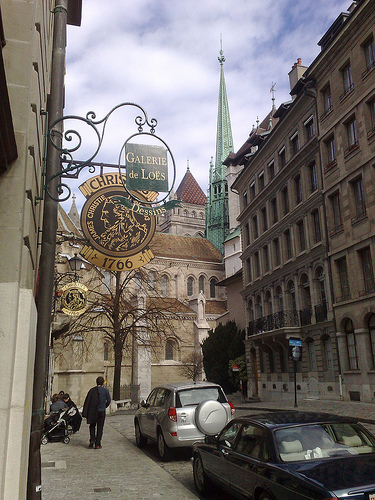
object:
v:
[140, 2, 296, 71]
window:
[253, 274, 315, 321]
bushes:
[204, 329, 244, 392]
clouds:
[105, 29, 201, 94]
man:
[79, 376, 120, 446]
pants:
[84, 414, 112, 447]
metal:
[103, 99, 187, 206]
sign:
[121, 135, 174, 203]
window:
[335, 309, 362, 379]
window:
[304, 200, 324, 252]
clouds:
[56, 0, 284, 102]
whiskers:
[105, 195, 180, 209]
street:
[104, 407, 374, 495]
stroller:
[40, 370, 110, 449]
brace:
[46, 97, 157, 204]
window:
[339, 111, 359, 160]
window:
[331, 254, 350, 303]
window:
[308, 205, 323, 249]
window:
[279, 184, 291, 216]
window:
[264, 158, 275, 181]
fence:
[244, 314, 302, 337]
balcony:
[245, 315, 303, 337]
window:
[288, 164, 306, 206]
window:
[291, 218, 312, 253]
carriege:
[37, 406, 84, 447]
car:
[128, 378, 236, 458]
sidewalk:
[87, 416, 203, 497]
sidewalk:
[36, 395, 214, 496]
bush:
[196, 308, 243, 395]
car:
[189, 409, 372, 498]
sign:
[72, 98, 177, 267]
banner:
[41, 154, 169, 275]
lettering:
[126, 148, 168, 182]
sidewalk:
[31, 448, 202, 499]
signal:
[284, 334, 307, 409]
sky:
[64, 3, 340, 168]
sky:
[78, 9, 292, 178]